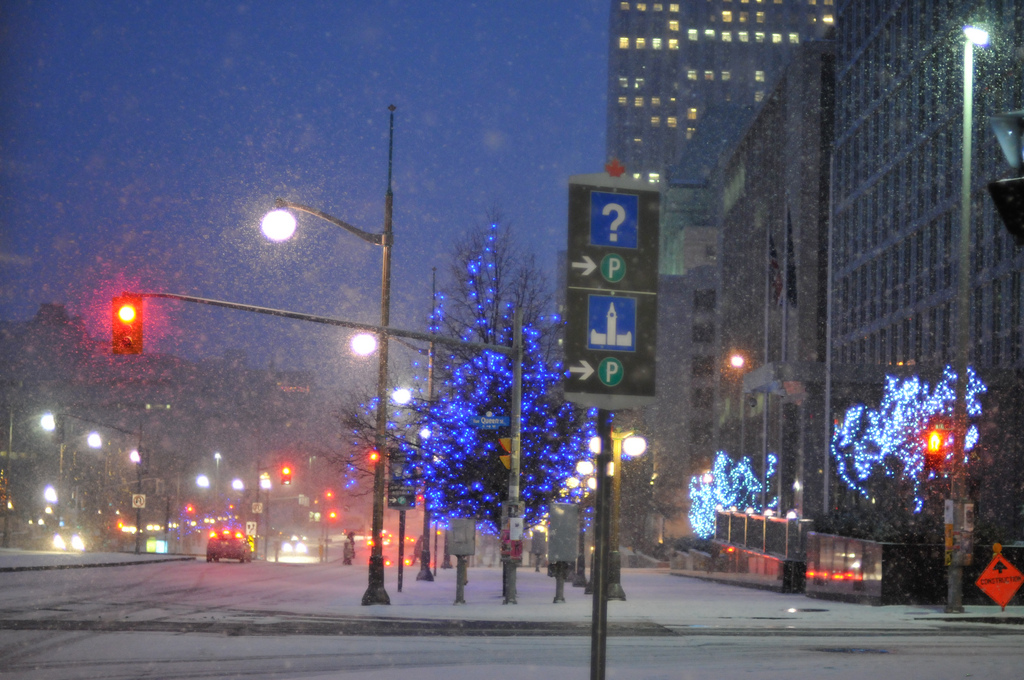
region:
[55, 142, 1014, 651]
this is a city street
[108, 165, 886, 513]
the weather is snowy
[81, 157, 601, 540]
the picture is blurry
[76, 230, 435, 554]
snow is falling on the street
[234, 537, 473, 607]
the sidewalk is covered in snow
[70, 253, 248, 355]
this is a traffic light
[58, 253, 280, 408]
the light is red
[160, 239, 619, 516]
the pole is metal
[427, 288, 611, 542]
the tree has lights in it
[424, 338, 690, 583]
the tree lights are blue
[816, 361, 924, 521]
lighted tree for decoration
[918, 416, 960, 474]
orange light on a pole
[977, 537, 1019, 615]
orange diamond shaped construction sign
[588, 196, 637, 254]
blue sign with a white question mark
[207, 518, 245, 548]
back lights on the car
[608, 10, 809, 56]
lighted windows on the building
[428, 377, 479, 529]
blue christmas lights on the tree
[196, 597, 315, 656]
snow on the road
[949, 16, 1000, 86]
lamp on the post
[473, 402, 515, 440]
blue and white sign on the pole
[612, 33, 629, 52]
a window on a building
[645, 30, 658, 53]
a window on a building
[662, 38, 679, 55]
a window on a building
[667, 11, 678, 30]
a window on a building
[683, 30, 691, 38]
a window on a building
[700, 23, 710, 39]
a window on a building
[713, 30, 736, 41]
a window on a building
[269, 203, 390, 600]
a black lamp post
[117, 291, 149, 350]
a red street light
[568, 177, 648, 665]
a street sign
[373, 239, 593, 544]
a tree with blue lights on it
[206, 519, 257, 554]
a car on the street